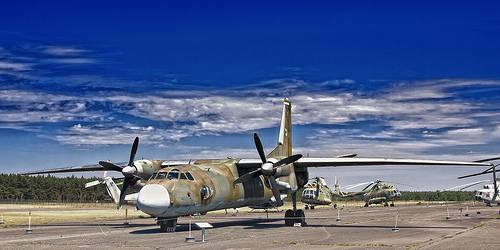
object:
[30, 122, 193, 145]
clouds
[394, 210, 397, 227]
pole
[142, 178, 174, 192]
rust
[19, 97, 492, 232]
plane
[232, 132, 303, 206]
blades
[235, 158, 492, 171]
wing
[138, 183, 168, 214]
nose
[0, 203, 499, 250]
pavement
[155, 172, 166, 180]
window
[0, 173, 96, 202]
trees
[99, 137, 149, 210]
propeller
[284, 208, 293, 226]
wheels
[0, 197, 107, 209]
fence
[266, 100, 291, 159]
tail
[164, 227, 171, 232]
wheels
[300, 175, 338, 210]
helicopter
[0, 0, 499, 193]
sky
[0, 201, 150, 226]
grass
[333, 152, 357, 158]
fin